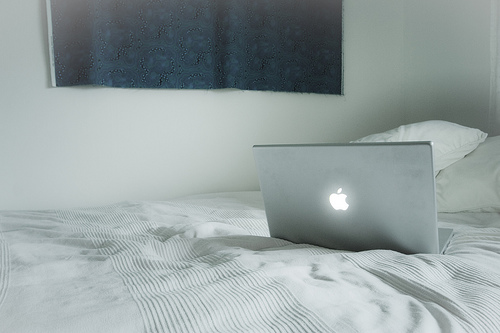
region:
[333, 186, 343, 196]
the stem of the apple logo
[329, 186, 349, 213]
the apple logo lit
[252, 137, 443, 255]
the top of the open laptop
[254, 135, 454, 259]
the silver open apple laptop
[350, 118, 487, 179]
the fluffy white pillow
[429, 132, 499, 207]
the fluffy white pillow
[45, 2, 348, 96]
the bottom of the blue curtain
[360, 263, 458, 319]
the fold in the blanket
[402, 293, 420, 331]
the fold in the blanket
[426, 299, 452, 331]
the fold in the blanket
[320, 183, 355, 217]
apple logo on a computer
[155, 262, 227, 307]
lines on a bed spread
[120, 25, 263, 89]
fabric hanging on a window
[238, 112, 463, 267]
silver apple lap top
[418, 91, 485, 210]
two pillows on a bed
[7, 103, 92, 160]
white paint on a wall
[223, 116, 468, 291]
lap top on a bed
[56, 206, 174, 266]
wrinkled blanket on a bed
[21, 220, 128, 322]
white comforter on a bed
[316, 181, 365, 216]
glowing logo on a computer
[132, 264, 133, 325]
Two white suit cases as toys.Two white suit cases as toys.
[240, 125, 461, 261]
open laptop on bed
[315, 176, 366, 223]
glowing apple on front of laptop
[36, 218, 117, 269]
wrinkle in bedding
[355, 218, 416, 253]
shadow on top of laptop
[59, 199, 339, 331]
ridged lines on bed spread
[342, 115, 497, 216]
pillows at head of bed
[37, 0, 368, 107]
grey curtain panel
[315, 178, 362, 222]
mac logo on front of laptop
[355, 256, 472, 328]
shadow on bedspread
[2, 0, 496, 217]
white walls in bedroom